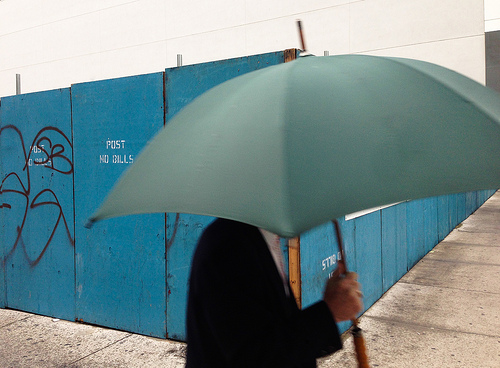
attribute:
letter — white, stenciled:
[98, 153, 106, 165]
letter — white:
[104, 138, 112, 150]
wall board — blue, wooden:
[0, 50, 499, 357]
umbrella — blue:
[87, 55, 498, 241]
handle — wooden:
[351, 329, 373, 368]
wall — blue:
[1, 87, 78, 322]